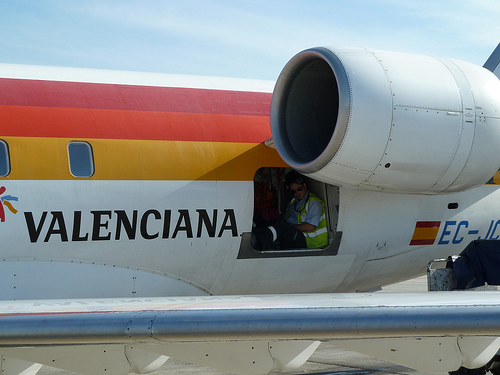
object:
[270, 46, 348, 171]
ring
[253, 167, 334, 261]
hole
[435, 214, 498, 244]
ec-jg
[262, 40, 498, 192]
engine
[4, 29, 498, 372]
plane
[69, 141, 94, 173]
window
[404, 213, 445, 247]
box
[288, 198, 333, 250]
vest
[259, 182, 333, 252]
man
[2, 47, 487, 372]
airplane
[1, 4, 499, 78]
clouds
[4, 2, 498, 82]
sky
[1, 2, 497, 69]
clouds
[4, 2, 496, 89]
clouds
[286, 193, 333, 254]
vest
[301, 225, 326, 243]
stripe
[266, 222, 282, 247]
stripe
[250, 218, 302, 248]
pants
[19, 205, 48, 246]
v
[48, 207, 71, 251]
letter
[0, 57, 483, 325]
plane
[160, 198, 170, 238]
letter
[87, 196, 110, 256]
letter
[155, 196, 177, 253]
letter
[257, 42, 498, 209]
engine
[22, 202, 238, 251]
word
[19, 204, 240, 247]
valencia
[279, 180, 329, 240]
crew member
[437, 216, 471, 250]
ec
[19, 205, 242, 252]
text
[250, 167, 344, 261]
door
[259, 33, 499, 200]
engine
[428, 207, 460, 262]
e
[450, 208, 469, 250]
c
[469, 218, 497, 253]
j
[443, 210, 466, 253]
e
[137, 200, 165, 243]
c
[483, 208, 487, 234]
j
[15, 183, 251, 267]
letters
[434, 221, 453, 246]
letters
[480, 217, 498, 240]
numbers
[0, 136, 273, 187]
striple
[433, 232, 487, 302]
baggage cart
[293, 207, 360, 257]
bag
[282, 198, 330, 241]
shirt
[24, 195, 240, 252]
sign